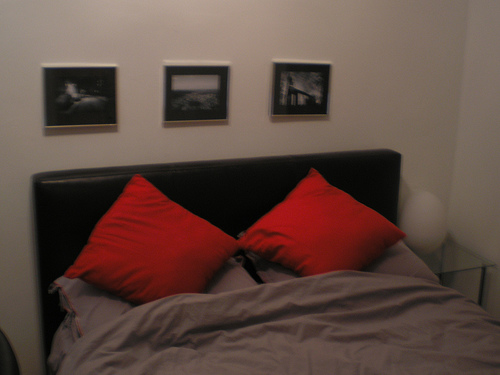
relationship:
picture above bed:
[15, 44, 340, 150] [110, 160, 495, 358]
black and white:
[119, 56, 258, 139] [182, 76, 208, 90]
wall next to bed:
[15, 44, 340, 150] [110, 160, 495, 358]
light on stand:
[343, 181, 477, 250] [186, 151, 480, 319]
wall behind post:
[380, 111, 414, 235] [7, 173, 66, 288]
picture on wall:
[15, 44, 340, 150] [380, 111, 414, 235]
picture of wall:
[15, 44, 340, 150] [380, 111, 414, 235]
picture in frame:
[15, 44, 340, 150] [3, 27, 437, 327]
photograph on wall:
[238, 64, 338, 115] [380, 111, 414, 235]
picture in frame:
[15, 44, 340, 150] [44, 55, 123, 144]